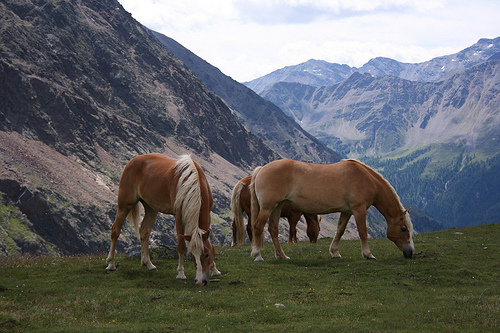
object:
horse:
[226, 168, 324, 247]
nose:
[195, 280, 206, 287]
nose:
[409, 250, 415, 259]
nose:
[310, 240, 316, 243]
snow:
[426, 44, 496, 81]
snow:
[296, 64, 328, 80]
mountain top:
[264, 40, 498, 87]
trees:
[472, 151, 499, 178]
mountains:
[432, 51, 498, 203]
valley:
[230, 72, 420, 208]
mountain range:
[1, 2, 498, 257]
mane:
[176, 152, 207, 249]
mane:
[360, 162, 405, 215]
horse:
[102, 150, 225, 286]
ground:
[364, 154, 419, 229]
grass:
[4, 228, 498, 330]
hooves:
[104, 261, 119, 274]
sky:
[116, 0, 498, 86]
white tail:
[230, 182, 246, 249]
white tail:
[247, 165, 264, 242]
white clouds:
[395, 17, 432, 52]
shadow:
[71, 260, 221, 297]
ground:
[0, 248, 494, 330]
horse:
[249, 153, 419, 262]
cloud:
[124, 2, 498, 75]